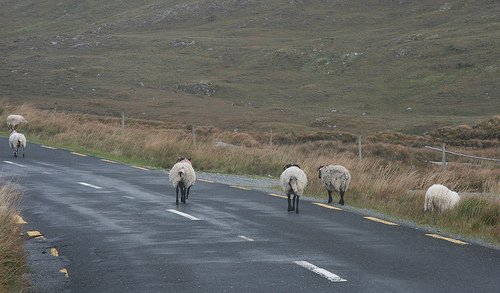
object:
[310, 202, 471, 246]
lines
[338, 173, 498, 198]
gate road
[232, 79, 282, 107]
grass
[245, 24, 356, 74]
hill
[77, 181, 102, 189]
stripe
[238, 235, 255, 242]
stripe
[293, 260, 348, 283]
stripe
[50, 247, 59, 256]
stripe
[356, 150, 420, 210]
grass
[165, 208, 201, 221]
line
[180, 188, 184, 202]
leg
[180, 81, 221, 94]
rocks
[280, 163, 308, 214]
sheep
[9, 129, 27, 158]
sheep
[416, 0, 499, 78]
grass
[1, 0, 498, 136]
hillside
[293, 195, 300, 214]
black legs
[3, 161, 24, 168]
white line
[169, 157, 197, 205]
sheep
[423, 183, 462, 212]
sheep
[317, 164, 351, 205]
sheep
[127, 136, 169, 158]
grass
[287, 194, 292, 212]
black leg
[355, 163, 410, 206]
tall grass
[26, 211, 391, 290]
road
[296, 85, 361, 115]
grass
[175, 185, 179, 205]
leg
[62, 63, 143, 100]
field